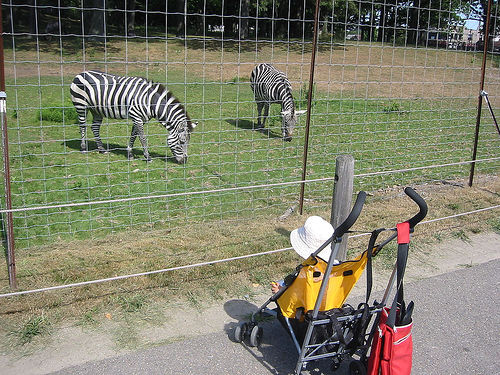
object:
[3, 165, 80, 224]
grass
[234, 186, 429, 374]
stroller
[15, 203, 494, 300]
forefront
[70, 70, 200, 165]
zebra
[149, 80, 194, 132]
mane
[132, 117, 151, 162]
leg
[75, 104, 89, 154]
leg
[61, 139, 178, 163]
shadow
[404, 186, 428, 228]
handle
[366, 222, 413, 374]
bag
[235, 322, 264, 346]
wheel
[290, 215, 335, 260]
hat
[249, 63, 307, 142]
zebra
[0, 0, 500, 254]
fence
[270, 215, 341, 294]
child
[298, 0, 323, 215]
post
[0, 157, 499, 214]
rope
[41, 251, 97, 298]
grass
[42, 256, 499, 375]
road